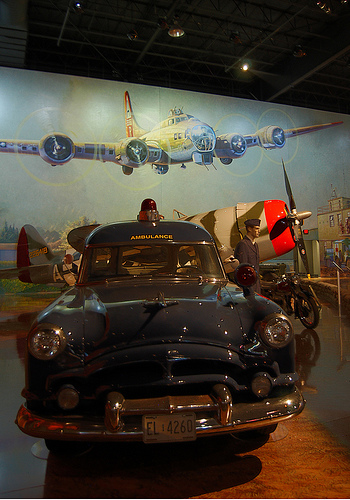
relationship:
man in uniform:
[234, 218, 261, 296] [233, 234, 260, 294]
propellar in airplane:
[275, 157, 316, 281] [2, 154, 316, 315]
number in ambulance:
[172, 419, 179, 435] [15, 197, 306, 453]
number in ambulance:
[187, 413, 192, 437] [15, 197, 306, 453]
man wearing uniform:
[240, 219, 263, 290] [230, 232, 265, 288]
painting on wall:
[0, 68, 350, 276] [287, 146, 311, 177]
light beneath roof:
[134, 194, 164, 224] [82, 219, 214, 249]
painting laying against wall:
[0, 68, 348, 337] [143, 99, 332, 307]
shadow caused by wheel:
[296, 327, 320, 366] [296, 289, 318, 332]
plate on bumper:
[38, 368, 290, 435] [18, 401, 322, 443]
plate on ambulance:
[38, 368, 290, 435] [15, 197, 306, 453]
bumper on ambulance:
[18, 401, 322, 443] [15, 197, 306, 453]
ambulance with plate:
[15, 197, 306, 453] [38, 368, 290, 435]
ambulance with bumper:
[15, 197, 306, 453] [18, 401, 322, 443]